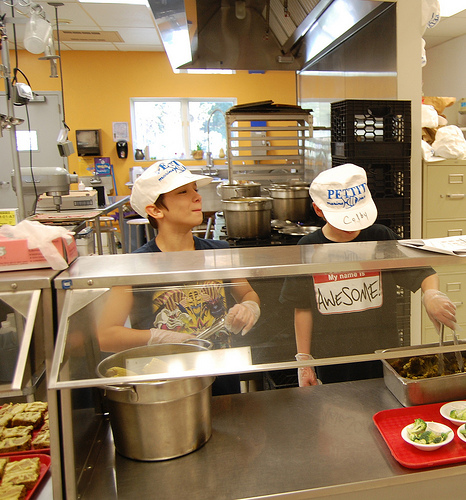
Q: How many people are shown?
A: Two.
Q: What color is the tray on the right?
A: Red.